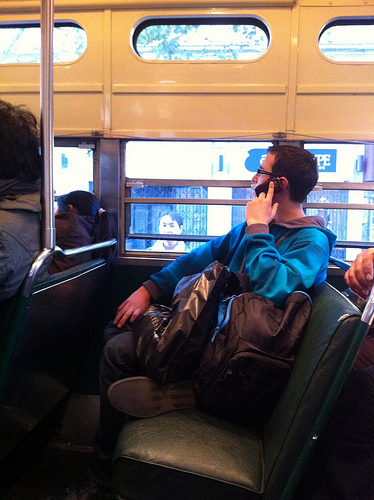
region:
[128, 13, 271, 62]
an oblong window on a train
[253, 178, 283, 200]
a black cell phone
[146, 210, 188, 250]
a man looking into the train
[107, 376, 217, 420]
the black sole of a shoe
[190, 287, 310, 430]
a blue and black bag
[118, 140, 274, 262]
a window on a passenger train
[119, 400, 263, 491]
the leather seat next to a man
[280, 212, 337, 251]
the flipped back hood of a sweater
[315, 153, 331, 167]
the letters PE on a sign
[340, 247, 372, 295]
a man's hand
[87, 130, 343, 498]
man on his cellphone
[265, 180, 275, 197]
index finger on the phone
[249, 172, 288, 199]
phone lifted up to the ear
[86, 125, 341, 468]
man sitting on a seat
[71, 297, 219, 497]
one leg on top of the other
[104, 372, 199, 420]
bottom of the shoe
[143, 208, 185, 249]
person visible through the window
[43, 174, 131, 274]
woman leaning on the window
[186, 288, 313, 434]
bag sitting on the seat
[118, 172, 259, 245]
metal rods on the window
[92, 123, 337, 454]
man sitting on a bus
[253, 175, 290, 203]
phone in man's hand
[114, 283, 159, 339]
right hand of a man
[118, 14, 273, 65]
top window of a bus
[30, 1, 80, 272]
pole on a bus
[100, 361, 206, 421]
sole of man's foot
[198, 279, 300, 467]
bag next to a man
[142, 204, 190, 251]
man outside a bus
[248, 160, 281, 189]
glasses on a man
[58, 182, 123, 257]
back of a woman's head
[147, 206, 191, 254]
The person outside the bus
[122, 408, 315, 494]
The seat is made of leather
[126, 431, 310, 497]
The seat is the color green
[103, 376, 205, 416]
The shoe of the man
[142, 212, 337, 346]
The man is wearing a blue sweater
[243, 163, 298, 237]
The man is on his cell phone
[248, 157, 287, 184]
The man is wearing glasses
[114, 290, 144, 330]
The hand of the man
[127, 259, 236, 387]
The man is holding a shopping bag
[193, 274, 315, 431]
The man has a backpack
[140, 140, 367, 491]
A person is riding the bus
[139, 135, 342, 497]
A person is using their cell phone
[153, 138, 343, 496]
A person is going to work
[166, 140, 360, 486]
A person has a backpack beside them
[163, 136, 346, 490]
A person has dark colored hair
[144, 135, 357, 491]
A person is sitting by a window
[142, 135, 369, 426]
A person is out in the daytime